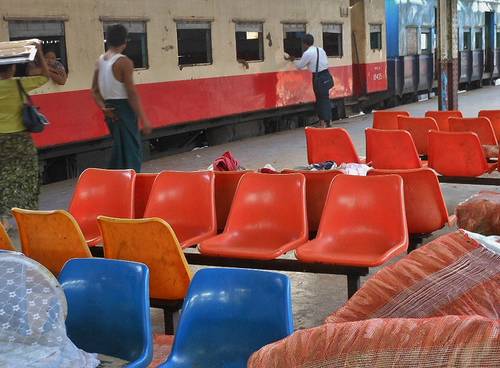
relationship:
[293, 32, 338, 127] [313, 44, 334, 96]
woman has pocketbook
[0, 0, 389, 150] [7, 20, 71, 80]
train car has window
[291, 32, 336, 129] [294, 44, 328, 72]
man dressed in a shirt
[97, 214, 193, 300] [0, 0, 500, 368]
seat at a train station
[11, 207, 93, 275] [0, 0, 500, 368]
seat at a train station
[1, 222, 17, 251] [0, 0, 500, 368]
seat at a train station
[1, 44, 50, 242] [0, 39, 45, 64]
woman carrying something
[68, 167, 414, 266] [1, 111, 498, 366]
four seats are in waiting area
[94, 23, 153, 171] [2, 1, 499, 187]
man looking at train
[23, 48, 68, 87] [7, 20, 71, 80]
person looking out window